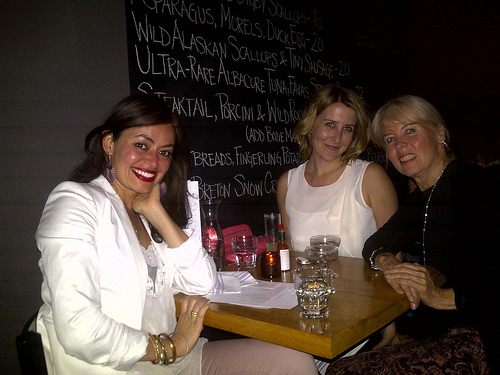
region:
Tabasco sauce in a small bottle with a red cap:
[277, 221, 290, 271]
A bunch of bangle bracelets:
[148, 326, 190, 367]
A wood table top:
[174, 253, 441, 360]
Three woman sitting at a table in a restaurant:
[29, 78, 499, 373]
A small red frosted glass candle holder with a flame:
[255, 247, 280, 281]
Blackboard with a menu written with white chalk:
[128, 2, 365, 210]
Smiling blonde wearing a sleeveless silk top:
[274, 78, 396, 249]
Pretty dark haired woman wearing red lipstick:
[32, 91, 222, 242]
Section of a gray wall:
[0, 1, 87, 126]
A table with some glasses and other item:
[173, 226, 443, 356]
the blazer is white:
[38, 175, 185, 365]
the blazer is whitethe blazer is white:
[41, 152, 196, 348]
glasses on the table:
[294, 255, 351, 323]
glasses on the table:
[278, 208, 352, 356]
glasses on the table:
[226, 215, 386, 355]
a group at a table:
[16, 89, 471, 355]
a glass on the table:
[290, 258, 335, 327]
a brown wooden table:
[235, 257, 394, 344]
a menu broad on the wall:
[147, 12, 346, 82]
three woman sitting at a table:
[37, 85, 472, 365]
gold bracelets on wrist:
[138, 329, 194, 365]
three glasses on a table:
[299, 231, 353, 331]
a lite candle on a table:
[257, 244, 279, 281]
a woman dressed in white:
[45, 117, 213, 329]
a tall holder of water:
[207, 186, 233, 271]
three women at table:
[42, 85, 479, 369]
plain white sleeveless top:
[277, 158, 378, 250]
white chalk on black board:
[132, 3, 349, 204]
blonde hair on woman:
[370, 96, 442, 178]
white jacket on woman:
[34, 177, 214, 369]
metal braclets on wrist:
[149, 330, 188, 367]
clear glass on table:
[292, 267, 338, 321]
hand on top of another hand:
[379, 260, 438, 309]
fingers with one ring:
[179, 297, 209, 321]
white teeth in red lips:
[130, 165, 157, 181]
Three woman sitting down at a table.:
[34, 86, 494, 372]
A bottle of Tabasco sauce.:
[276, 225, 292, 272]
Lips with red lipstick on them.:
[129, 162, 161, 183]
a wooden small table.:
[207, 248, 449, 360]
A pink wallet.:
[214, 224, 279, 266]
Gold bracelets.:
[146, 328, 181, 367]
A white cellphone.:
[295, 250, 314, 267]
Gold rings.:
[189, 308, 199, 319]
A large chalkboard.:
[126, 22, 390, 240]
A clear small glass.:
[294, 268, 332, 318]